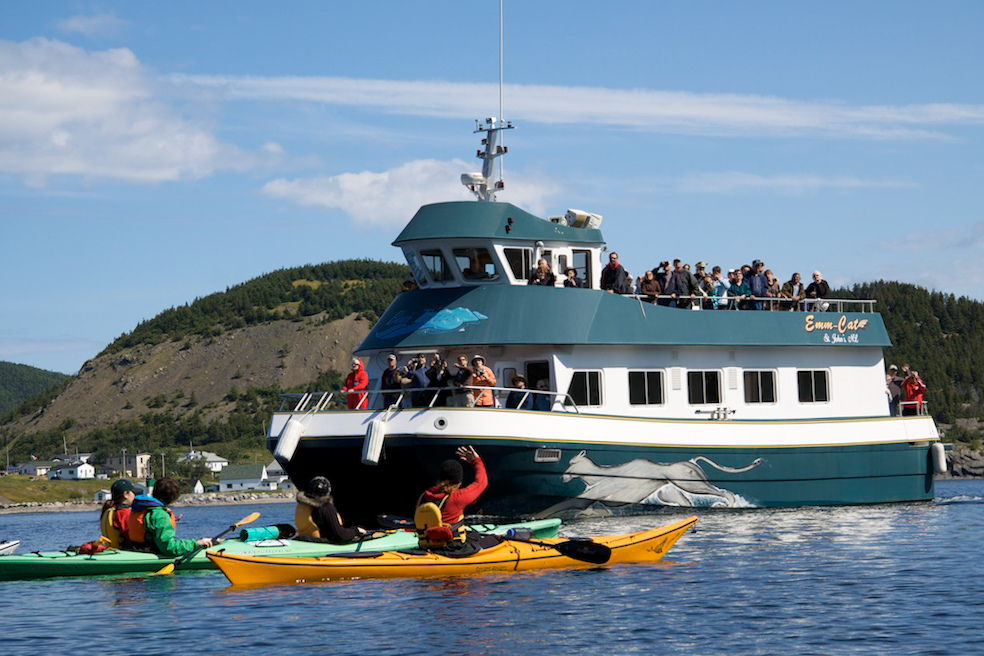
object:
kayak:
[207, 518, 701, 590]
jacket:
[126, 496, 202, 559]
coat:
[342, 360, 369, 400]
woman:
[126, 478, 214, 555]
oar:
[153, 511, 260, 579]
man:
[413, 446, 496, 557]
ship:
[263, 0, 944, 518]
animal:
[528, 450, 763, 521]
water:
[2, 476, 984, 653]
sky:
[0, 3, 982, 369]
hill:
[0, 238, 419, 476]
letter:
[804, 314, 815, 332]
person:
[465, 353, 497, 406]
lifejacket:
[295, 491, 342, 538]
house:
[47, 460, 95, 479]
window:
[687, 372, 719, 404]